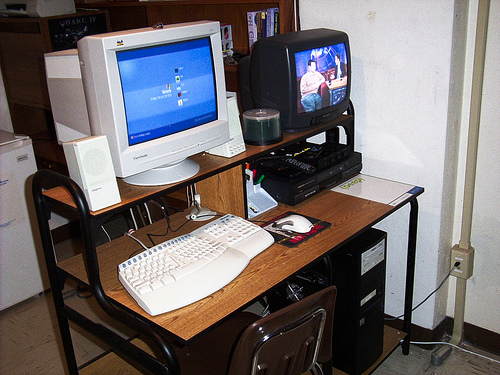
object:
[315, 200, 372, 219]
table surface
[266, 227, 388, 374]
computer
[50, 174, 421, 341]
desk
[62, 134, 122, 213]
speaker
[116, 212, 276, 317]
key board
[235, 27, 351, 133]
t.v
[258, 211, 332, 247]
mouse pad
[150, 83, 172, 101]
windows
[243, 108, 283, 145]
cd holder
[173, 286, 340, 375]
brown chair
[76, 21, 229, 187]
computer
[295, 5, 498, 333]
wall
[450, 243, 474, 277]
outlet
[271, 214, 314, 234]
mouse